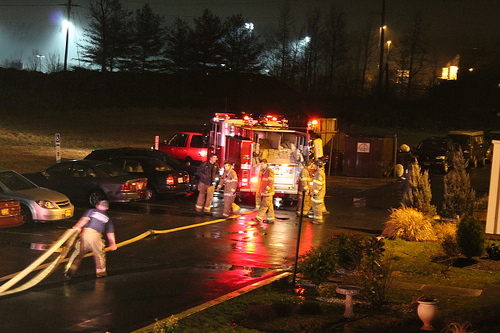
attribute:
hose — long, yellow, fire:
[105, 187, 237, 292]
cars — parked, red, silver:
[16, 171, 185, 250]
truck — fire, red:
[178, 72, 368, 229]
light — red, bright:
[235, 143, 270, 207]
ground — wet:
[137, 240, 195, 301]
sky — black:
[171, 12, 193, 24]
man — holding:
[66, 202, 120, 272]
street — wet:
[150, 217, 233, 290]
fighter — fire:
[53, 183, 125, 279]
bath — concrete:
[163, 244, 203, 285]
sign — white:
[350, 138, 382, 158]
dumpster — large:
[301, 92, 390, 168]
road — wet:
[184, 213, 262, 272]